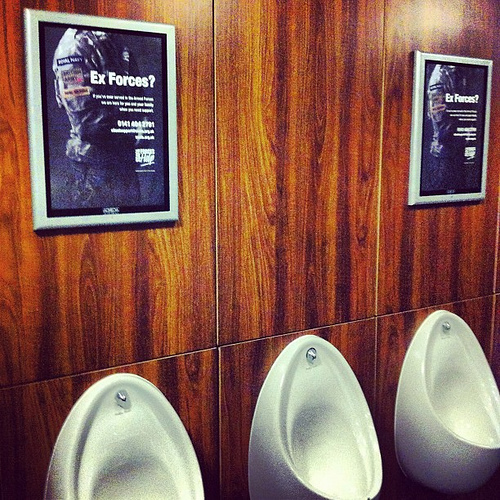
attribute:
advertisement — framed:
[20, 7, 185, 231]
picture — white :
[412, 47, 498, 208]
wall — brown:
[0, 6, 495, 499]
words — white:
[88, 68, 162, 125]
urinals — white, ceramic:
[47, 307, 497, 494]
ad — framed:
[13, 4, 191, 244]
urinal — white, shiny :
[51, 369, 209, 498]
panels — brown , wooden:
[200, 102, 407, 265]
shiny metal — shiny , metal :
[440, 319, 452, 330]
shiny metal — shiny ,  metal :
[307, 347, 317, 364]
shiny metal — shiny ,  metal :
[113, 390, 130, 407]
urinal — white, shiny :
[393, 308, 499, 493]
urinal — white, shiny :
[247, 333, 383, 499]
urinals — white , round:
[62, 294, 477, 499]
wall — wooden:
[9, 0, 482, 420]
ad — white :
[403, 49, 490, 218]